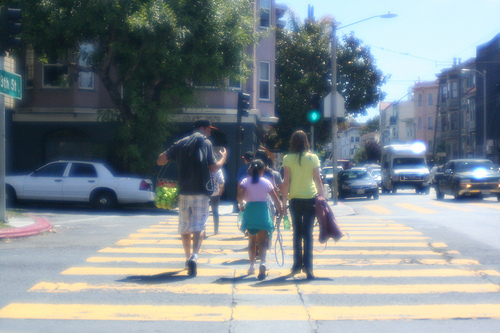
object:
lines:
[0, 212, 500, 321]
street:
[0, 197, 500, 332]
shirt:
[282, 150, 321, 199]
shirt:
[239, 177, 273, 202]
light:
[305, 107, 324, 126]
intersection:
[47, 199, 500, 333]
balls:
[154, 187, 178, 209]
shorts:
[177, 192, 211, 234]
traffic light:
[233, 90, 250, 172]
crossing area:
[0, 209, 500, 322]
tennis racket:
[275, 210, 286, 267]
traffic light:
[305, 106, 322, 142]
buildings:
[333, 32, 498, 162]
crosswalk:
[362, 191, 498, 218]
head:
[247, 158, 267, 178]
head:
[290, 129, 311, 154]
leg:
[192, 206, 205, 258]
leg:
[258, 231, 268, 265]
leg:
[300, 208, 314, 265]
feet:
[186, 254, 198, 278]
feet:
[257, 264, 269, 280]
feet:
[285, 260, 316, 280]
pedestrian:
[154, 118, 230, 279]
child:
[236, 158, 282, 277]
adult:
[280, 129, 325, 280]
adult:
[157, 118, 227, 280]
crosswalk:
[0, 202, 500, 330]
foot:
[186, 255, 199, 279]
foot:
[257, 263, 268, 281]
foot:
[300, 261, 319, 280]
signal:
[304, 91, 324, 125]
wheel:
[92, 188, 120, 209]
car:
[0, 157, 159, 211]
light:
[138, 179, 157, 192]